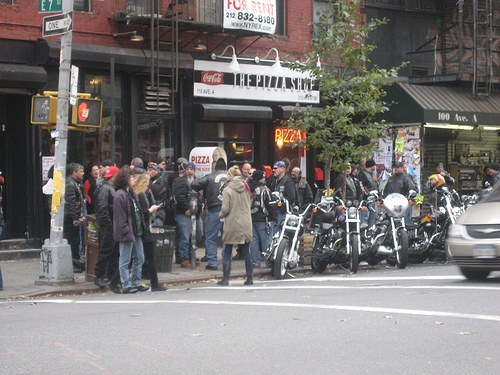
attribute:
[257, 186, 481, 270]
motorcycles — parked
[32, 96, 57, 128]
pedestrian crossing — signal, lit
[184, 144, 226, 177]
pizza sign — neon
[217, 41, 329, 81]
lights — white, hanging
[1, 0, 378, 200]
building — red, brick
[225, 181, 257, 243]
jacket — hooded, light brown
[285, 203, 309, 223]
windshield — little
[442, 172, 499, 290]
car — silver, beige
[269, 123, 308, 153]
pizza sign — neon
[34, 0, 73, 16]
street sign — green